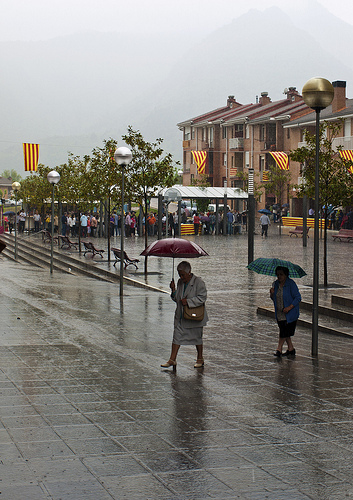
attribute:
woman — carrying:
[154, 261, 218, 363]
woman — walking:
[266, 264, 301, 360]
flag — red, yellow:
[19, 139, 41, 177]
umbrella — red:
[136, 234, 209, 259]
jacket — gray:
[169, 271, 210, 331]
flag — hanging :
[187, 149, 215, 176]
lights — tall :
[10, 144, 134, 302]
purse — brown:
[168, 298, 220, 334]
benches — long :
[9, 221, 137, 275]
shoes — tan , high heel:
[160, 358, 204, 368]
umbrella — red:
[136, 240, 207, 257]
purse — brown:
[178, 296, 207, 322]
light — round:
[112, 145, 132, 170]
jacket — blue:
[263, 272, 307, 321]